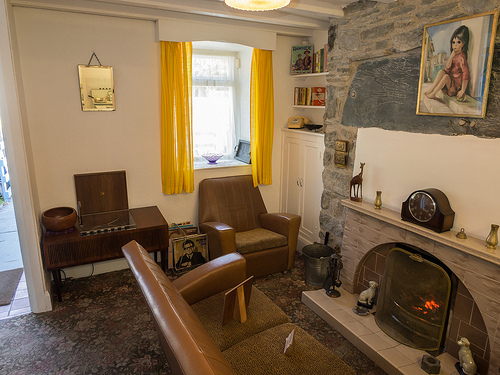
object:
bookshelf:
[287, 32, 327, 130]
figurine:
[349, 161, 365, 202]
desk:
[39, 205, 169, 271]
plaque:
[77, 64, 116, 113]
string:
[87, 52, 102, 67]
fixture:
[220, 0, 293, 12]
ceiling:
[4, 0, 360, 23]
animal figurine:
[359, 281, 379, 306]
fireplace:
[300, 197, 499, 375]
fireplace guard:
[372, 247, 452, 353]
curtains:
[249, 46, 274, 187]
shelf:
[292, 104, 327, 110]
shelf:
[293, 72, 330, 78]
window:
[174, 44, 251, 174]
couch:
[122, 239, 362, 375]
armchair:
[199, 174, 302, 280]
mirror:
[77, 51, 116, 112]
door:
[0, 120, 40, 320]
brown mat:
[0, 266, 25, 305]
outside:
[0, 115, 46, 325]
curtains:
[159, 40, 196, 195]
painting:
[417, 14, 496, 116]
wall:
[7, 0, 500, 287]